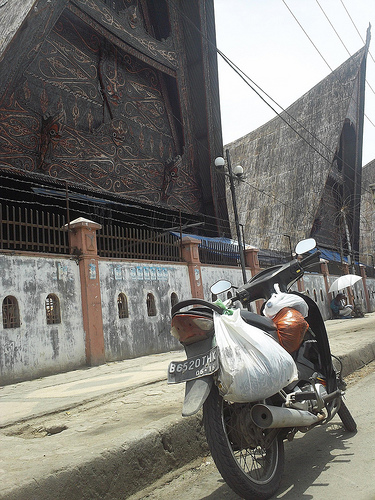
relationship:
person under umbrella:
[329, 292, 352, 317] [327, 272, 362, 293]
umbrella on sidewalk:
[327, 272, 362, 293] [0, 311, 373, 491]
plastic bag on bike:
[260, 281, 311, 318] [165, 234, 354, 500]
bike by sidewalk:
[165, 234, 354, 500] [1, 312, 373, 457]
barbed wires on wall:
[0, 175, 373, 264] [2, 220, 373, 382]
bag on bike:
[212, 298, 297, 403] [165, 234, 354, 500]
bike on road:
[165, 234, 354, 500] [136, 356, 371, 498]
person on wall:
[329, 292, 353, 318] [300, 274, 351, 315]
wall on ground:
[300, 274, 351, 315] [321, 316, 372, 331]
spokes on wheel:
[226, 406, 277, 486] [198, 373, 294, 498]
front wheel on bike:
[325, 389, 358, 436] [151, 232, 364, 496]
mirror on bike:
[294, 237, 318, 254] [165, 234, 354, 500]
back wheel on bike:
[203, 384, 284, 495] [165, 234, 354, 500]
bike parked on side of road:
[165, 234, 354, 500] [136, 356, 371, 498]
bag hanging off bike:
[212, 298, 297, 403] [165, 236, 356, 499]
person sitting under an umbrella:
[329, 292, 353, 318] [329, 266, 361, 294]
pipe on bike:
[244, 383, 316, 444] [186, 220, 371, 493]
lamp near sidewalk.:
[213, 152, 253, 276] [19, 328, 253, 451]